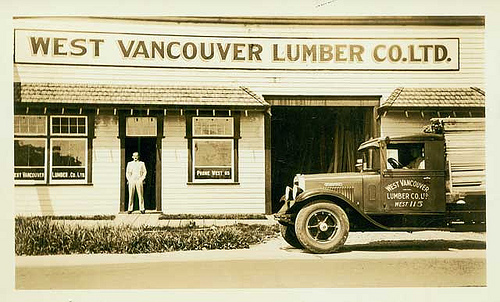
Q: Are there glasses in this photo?
A: No, there are no glasses.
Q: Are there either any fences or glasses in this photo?
A: No, there are no glasses or fences.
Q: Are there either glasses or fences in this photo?
A: No, there are no glasses or fences.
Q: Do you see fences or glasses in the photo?
A: No, there are no glasses or fences.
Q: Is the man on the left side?
A: Yes, the man is on the left of the image.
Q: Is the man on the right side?
A: No, the man is on the left of the image.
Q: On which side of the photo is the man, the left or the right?
A: The man is on the left of the image.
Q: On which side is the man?
A: The man is on the left of the image.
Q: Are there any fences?
A: No, there are no fences.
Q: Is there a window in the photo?
A: Yes, there is a window.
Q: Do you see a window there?
A: Yes, there is a window.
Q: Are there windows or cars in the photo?
A: Yes, there is a window.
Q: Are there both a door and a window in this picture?
A: Yes, there are both a window and a door.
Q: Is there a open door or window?
A: Yes, there is an open window.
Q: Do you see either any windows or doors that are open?
A: Yes, the window is open.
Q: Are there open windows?
A: Yes, there is an open window.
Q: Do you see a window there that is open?
A: Yes, there is a window that is open.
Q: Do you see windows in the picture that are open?
A: Yes, there is a window that is open.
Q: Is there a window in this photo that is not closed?
A: Yes, there is a open window.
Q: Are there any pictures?
A: No, there are no pictures.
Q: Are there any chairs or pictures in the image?
A: No, there are no pictures or chairs.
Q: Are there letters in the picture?
A: Yes, there are letters.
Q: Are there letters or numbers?
A: Yes, there are letters.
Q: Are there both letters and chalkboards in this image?
A: No, there are letters but no chalkboards.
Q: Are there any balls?
A: No, there are no balls.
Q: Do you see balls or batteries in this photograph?
A: No, there are no balls or batteries.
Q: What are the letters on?
A: The letters are on the sign.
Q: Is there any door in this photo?
A: Yes, there is a door.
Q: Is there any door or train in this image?
A: Yes, there is a door.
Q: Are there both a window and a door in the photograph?
A: Yes, there are both a door and a window.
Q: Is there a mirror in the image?
A: No, there are no mirrors.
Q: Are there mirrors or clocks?
A: No, there are no mirrors or clocks.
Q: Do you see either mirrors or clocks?
A: No, there are no mirrors or clocks.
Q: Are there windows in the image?
A: Yes, there are windows.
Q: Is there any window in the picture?
A: Yes, there are windows.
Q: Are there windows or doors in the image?
A: Yes, there are windows.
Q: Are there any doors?
A: Yes, there is a door.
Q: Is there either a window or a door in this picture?
A: Yes, there is a door.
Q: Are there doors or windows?
A: Yes, there is a door.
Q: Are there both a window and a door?
A: Yes, there are both a door and a window.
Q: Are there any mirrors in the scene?
A: No, there are no mirrors.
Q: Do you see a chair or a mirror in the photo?
A: No, there are no mirrors or chairs.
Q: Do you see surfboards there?
A: No, there are no surfboards.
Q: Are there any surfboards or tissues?
A: No, there are no surfboards or tissues.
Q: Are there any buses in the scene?
A: No, there are no buses.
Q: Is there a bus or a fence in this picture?
A: No, there are no buses or fences.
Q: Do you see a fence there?
A: No, there are no fences.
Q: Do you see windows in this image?
A: Yes, there are windows.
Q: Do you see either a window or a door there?
A: Yes, there are windows.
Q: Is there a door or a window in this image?
A: Yes, there are windows.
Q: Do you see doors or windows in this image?
A: Yes, there are windows.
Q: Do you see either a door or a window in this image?
A: Yes, there are windows.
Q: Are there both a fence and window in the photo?
A: No, there are windows but no fences.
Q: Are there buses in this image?
A: No, there are no buses.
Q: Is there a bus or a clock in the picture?
A: No, there are no buses or clocks.